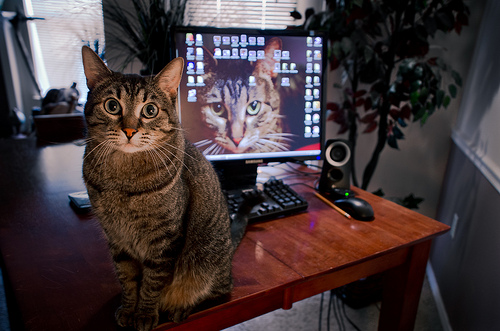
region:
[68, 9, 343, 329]
a live cat featured with the desktop background cat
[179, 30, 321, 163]
black computer monitor with cat background picture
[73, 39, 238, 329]
perky eared cat sitting on a desk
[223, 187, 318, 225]
black computer keyboard on top of the desk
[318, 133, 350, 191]
black and silver computer webcam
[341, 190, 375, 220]
black computer mouse on the desk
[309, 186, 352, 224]
yellow #2 pencil sitting on the desk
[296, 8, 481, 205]
decorative indoor tree in the corner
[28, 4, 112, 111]
window with mini-blinds allowing the sun in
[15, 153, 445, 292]
glossy brown table top style desk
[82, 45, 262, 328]
a kitten sitting on a table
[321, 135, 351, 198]
a black speaker on a table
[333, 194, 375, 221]
a black mouse on a table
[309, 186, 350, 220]
a yellow pencil on a table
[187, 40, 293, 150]
picture of a kitten on a computer screen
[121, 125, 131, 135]
orange nose of a kitten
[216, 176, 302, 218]
black keyboard on a table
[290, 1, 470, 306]
an indoor green tree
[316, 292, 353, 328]
a bunch of black wires on the floor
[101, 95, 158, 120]
green eyes of a kitten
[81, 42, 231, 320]
Cat sitting on desk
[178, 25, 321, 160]
Computer monitor with cat wallpaper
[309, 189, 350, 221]
Yellow number two pencil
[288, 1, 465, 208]
Decorative tree in corner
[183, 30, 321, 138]
Desktop icons on screen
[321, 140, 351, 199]
Black computer speaker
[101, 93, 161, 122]
Cat's very big eyes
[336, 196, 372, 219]
Black computer mouse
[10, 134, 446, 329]
Brown smooth wooden table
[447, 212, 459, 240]
White electrical outlet in wall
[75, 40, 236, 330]
Cat sitting on wooden desk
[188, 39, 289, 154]
Picture of cat on monitor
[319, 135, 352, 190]
Black speaker next to monitor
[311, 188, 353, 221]
Pencil next to black mouse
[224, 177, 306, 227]
Black keyboard below monitor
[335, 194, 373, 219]
Black mouse on wooden table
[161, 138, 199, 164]
White whisker on cat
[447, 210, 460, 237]
White electrical outlet on wall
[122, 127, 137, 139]
Orange nose on cat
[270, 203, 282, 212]
Black key on keyboard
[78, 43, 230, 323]
an adult brown and black cat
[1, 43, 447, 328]
cat is sitting on a wooden table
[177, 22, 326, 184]
large computer monitor on table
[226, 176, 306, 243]
cat's tail on computer keyboard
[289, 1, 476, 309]
leafy tall plant against a wall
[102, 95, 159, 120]
cat's eyes are large and round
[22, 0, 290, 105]
plant in background between two windows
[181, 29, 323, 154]
image of cat serving as computer wallpaper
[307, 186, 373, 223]
yellow pencil next to computer mouse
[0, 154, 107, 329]
part of table is in shadow